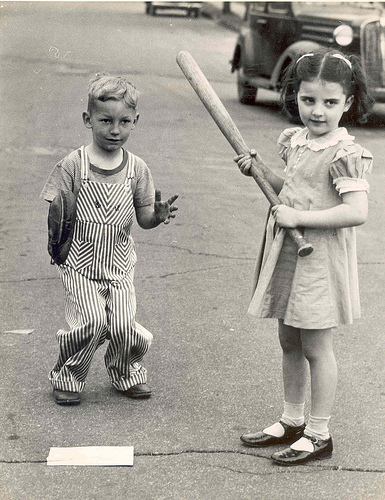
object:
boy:
[42, 69, 179, 408]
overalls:
[43, 148, 160, 399]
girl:
[237, 47, 371, 476]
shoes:
[273, 432, 331, 466]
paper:
[45, 444, 135, 467]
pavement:
[3, 414, 203, 498]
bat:
[170, 45, 317, 260]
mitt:
[45, 197, 79, 256]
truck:
[227, 3, 384, 130]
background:
[2, 3, 385, 135]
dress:
[247, 121, 373, 335]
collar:
[285, 121, 360, 159]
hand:
[152, 190, 180, 223]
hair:
[88, 74, 141, 120]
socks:
[288, 414, 340, 456]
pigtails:
[325, 47, 370, 126]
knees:
[66, 303, 106, 347]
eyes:
[299, 90, 312, 111]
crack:
[1, 429, 385, 487]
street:
[2, 3, 385, 496]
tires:
[235, 47, 258, 104]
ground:
[2, 419, 385, 496]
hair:
[280, 47, 361, 134]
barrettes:
[292, 48, 357, 73]